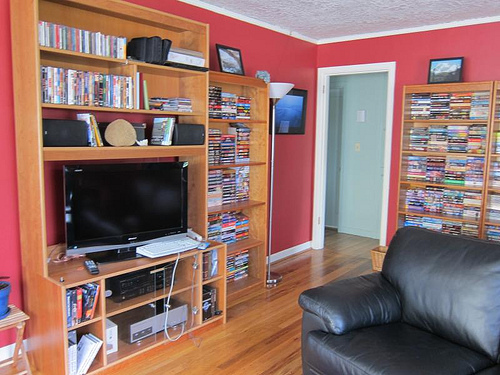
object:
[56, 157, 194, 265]
television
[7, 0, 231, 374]
center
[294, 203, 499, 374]
sofa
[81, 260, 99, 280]
control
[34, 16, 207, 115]
books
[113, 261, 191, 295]
dvr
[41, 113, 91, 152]
speaker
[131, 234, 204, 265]
keyboard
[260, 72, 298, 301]
lamp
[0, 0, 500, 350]
wall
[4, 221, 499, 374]
floor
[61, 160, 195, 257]
screen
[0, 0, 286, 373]
mantel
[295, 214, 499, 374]
couch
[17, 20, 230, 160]
shelf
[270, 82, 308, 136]
portrait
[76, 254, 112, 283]
remote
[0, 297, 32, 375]
table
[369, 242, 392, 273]
can